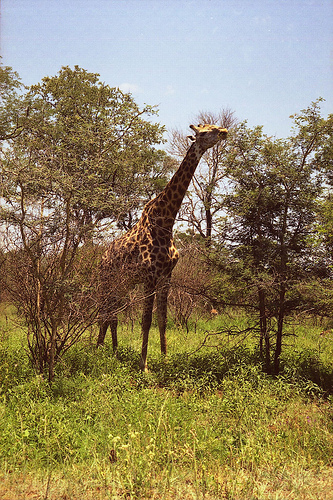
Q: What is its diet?
A: Vegetarian.